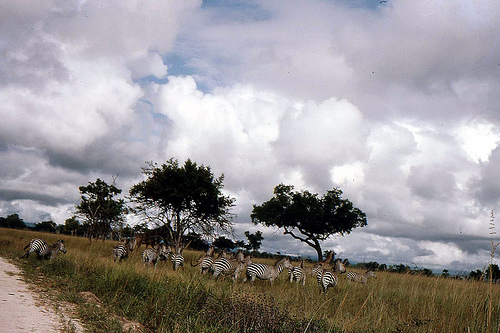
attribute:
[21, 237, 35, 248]
zebras tail — zebra's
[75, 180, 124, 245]
green trees — dark green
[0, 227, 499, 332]
grassy field — large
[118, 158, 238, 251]
green trees — dark green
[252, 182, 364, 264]
green trees — dark green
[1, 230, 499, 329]
field — large, grassy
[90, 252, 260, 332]
field — grassy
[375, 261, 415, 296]
grass — green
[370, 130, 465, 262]
clouds — thick, white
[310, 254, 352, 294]
zebra — striped, white, black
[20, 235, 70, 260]
zebra — black, white, striped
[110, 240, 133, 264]
zebra — black, white, striped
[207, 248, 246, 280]
zebra — black, white, striped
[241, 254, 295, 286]
zebra — black, white, striped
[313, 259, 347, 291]
zebra — black, white, striped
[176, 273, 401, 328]
grass — tall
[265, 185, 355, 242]
branch — long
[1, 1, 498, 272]
sky — blue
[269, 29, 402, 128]
clouds — white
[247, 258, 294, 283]
zebra — black, white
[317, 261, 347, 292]
zebra — black, white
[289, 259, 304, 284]
zebra — black, white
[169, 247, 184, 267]
zebra — black, white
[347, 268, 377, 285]
zebra — black, white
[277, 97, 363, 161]
clouds — white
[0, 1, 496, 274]
clouds — big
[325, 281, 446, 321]
grass — tall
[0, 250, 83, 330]
dirt road — white, dusty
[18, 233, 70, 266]
zebra — black, white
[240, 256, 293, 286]
zebra — white, black, striped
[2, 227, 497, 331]
grass — tall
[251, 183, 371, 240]
top — dark